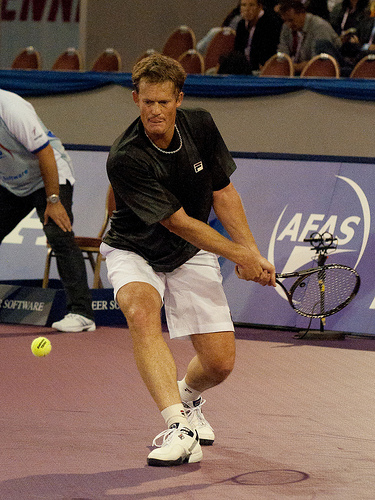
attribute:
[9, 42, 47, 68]
chair — padded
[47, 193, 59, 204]
watch — silver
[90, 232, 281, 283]
shorts — white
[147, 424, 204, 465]
shoe — black, white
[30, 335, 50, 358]
ball — yellow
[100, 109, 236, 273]
t shirt — black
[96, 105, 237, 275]
tshirt — black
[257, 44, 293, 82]
seat — brown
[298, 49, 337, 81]
seat — brown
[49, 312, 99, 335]
shoe — black, white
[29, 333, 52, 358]
ball — yellow green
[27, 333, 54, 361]
ball — lime green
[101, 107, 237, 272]
shirt — black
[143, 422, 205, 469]
shoes — white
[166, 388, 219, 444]
shoes — white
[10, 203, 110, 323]
pants — black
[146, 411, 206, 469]
shoe — black, white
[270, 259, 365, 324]
racquet — black, gold